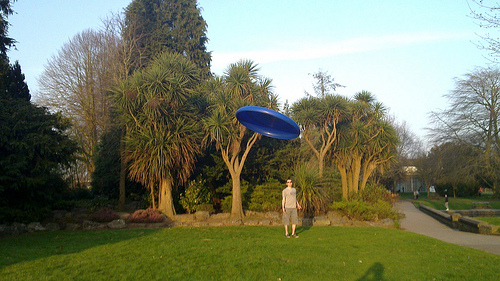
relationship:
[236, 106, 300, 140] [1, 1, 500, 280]
frisbee in air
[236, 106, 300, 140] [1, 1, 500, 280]
frisbee flying in air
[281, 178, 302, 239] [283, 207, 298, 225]
man wearing shorts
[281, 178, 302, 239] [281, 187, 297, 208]
man wearing shirt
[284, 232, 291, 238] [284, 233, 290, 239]
shoe on foot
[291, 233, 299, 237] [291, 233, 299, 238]
shoe on foot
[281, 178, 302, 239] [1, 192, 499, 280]
man standing in grass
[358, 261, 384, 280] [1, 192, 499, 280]
shadow on top of grass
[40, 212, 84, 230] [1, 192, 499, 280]
bed by grass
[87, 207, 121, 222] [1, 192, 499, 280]
bed by grass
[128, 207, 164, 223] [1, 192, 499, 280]
bed by grass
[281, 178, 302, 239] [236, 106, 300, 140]
man threw frisbee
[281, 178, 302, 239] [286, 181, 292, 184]
man wearing sunglasses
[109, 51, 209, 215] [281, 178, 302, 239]
tree behind man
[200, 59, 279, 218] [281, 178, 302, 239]
tree behind man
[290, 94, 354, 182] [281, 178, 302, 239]
tree behind man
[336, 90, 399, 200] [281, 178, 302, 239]
tree behind man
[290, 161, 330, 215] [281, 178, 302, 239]
tree behind man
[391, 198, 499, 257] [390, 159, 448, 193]
sidewalk leads to residence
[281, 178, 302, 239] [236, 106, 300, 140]
man watching frisbee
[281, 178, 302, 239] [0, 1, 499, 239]
man in background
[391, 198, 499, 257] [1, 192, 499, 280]
sidewalk next to grass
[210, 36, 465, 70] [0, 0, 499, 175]
cloud in sky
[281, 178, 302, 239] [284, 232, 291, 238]
man has shoe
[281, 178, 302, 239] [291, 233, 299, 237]
man has shoe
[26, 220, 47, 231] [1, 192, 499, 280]
rock behind grass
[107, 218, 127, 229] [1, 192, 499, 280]
rock behind grass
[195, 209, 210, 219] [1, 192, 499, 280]
rock behind grass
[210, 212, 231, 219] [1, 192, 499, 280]
rock behind grass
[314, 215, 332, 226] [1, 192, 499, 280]
rock behind grass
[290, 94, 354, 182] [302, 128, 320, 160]
tree has branch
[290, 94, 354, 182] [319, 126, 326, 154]
tree has branch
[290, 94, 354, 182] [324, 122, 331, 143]
tree has branch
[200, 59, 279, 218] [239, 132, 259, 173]
tree has branch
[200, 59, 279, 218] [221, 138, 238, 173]
tree has branch